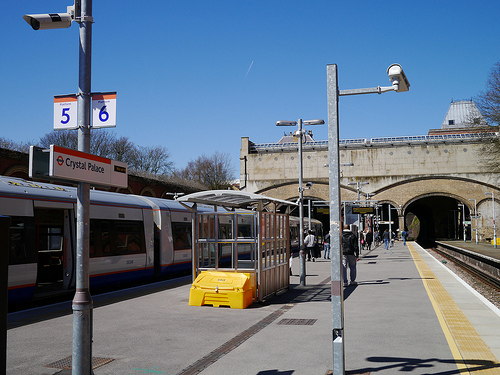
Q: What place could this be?
A: It is a station.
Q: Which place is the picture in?
A: It is at the station.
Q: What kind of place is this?
A: It is a station.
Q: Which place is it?
A: It is a station.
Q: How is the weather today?
A: It is clear.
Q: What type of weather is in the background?
A: It is clear.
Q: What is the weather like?
A: It is clear.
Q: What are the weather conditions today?
A: It is clear.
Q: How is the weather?
A: It is clear.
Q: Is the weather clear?
A: Yes, it is clear.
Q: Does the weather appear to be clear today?
A: Yes, it is clear.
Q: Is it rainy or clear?
A: It is clear.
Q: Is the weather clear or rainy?
A: It is clear.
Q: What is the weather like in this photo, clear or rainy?
A: It is clear.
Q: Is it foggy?
A: No, it is clear.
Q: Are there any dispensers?
A: No, there are no dispensers.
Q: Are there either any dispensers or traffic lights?
A: No, there are no dispensers or traffic lights.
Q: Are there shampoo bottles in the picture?
A: No, there are no shampoo bottles.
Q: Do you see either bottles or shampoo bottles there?
A: No, there are no shampoo bottles or bottles.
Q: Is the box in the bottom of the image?
A: Yes, the box is in the bottom of the image.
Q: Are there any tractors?
A: No, there are no tractors.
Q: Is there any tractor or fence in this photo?
A: No, there are no tractors or fences.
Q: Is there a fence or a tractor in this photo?
A: No, there are no tractors or fences.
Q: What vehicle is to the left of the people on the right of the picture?
A: The vehicle is a car.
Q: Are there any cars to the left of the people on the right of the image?
A: Yes, there is a car to the left of the people.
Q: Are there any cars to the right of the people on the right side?
A: No, the car is to the left of the people.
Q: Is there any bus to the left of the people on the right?
A: No, there is a car to the left of the people.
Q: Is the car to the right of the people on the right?
A: No, the car is to the left of the people.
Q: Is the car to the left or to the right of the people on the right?
A: The car is to the left of the people.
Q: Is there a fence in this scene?
A: No, there are no fences.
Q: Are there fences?
A: No, there are no fences.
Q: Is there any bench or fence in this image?
A: No, there are no fences or benches.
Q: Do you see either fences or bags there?
A: No, there are no fences or bags.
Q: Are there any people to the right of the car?
A: Yes, there are people to the right of the car.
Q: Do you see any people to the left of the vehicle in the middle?
A: No, the people are to the right of the car.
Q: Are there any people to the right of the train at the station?
A: Yes, there are people to the right of the train.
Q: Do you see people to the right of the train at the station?
A: Yes, there are people to the right of the train.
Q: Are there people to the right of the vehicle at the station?
A: Yes, there are people to the right of the train.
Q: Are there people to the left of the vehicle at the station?
A: No, the people are to the right of the train.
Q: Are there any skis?
A: No, there are no skis.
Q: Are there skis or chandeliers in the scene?
A: No, there are no skis or chandeliers.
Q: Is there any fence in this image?
A: No, there are no fences.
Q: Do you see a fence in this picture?
A: No, there are no fences.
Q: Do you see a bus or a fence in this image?
A: No, there are no fences or buses.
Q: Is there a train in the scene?
A: Yes, there is a train.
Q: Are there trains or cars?
A: Yes, there is a train.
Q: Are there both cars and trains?
A: Yes, there are both a train and a car.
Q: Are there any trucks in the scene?
A: No, there are no trucks.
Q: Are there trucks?
A: No, there are no trucks.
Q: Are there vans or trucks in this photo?
A: No, there are no trucks or vans.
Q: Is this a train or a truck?
A: This is a train.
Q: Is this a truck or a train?
A: This is a train.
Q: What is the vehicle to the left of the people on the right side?
A: The vehicle is a train.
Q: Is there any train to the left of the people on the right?
A: Yes, there is a train to the left of the people.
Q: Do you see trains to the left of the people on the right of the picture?
A: Yes, there is a train to the left of the people.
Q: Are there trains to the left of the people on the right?
A: Yes, there is a train to the left of the people.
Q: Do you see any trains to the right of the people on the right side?
A: No, the train is to the left of the people.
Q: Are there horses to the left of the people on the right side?
A: No, there is a train to the left of the people.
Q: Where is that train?
A: The train is at the station.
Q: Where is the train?
A: The train is at the station.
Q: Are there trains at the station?
A: Yes, there is a train at the station.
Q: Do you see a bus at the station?
A: No, there is a train at the station.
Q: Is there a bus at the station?
A: No, there is a train at the station.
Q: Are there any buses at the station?
A: No, there is a train at the station.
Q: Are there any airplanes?
A: No, there are no airplanes.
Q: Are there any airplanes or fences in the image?
A: No, there are no airplanes or fences.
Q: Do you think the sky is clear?
A: Yes, the sky is clear.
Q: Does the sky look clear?
A: Yes, the sky is clear.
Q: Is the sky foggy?
A: No, the sky is clear.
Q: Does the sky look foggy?
A: No, the sky is clear.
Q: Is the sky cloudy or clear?
A: The sky is clear.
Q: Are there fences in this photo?
A: No, there are no fences.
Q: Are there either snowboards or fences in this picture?
A: No, there are no fences or snowboards.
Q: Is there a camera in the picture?
A: Yes, there is a camera.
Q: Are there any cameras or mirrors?
A: Yes, there is a camera.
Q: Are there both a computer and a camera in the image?
A: No, there is a camera but no computers.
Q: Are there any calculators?
A: No, there are no calculators.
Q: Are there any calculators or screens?
A: No, there are no calculators or screens.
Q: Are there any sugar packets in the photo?
A: No, there are no sugar packets.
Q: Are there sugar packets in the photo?
A: No, there are no sugar packets.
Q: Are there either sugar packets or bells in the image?
A: No, there are no sugar packets or bells.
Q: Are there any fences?
A: No, there are no fences.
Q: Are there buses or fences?
A: No, there are no fences or buses.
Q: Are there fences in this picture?
A: No, there are no fences.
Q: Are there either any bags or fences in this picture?
A: No, there are no fences or bags.